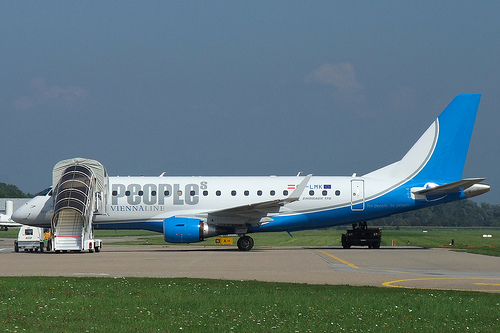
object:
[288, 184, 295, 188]
flag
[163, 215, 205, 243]
engine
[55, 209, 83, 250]
stairs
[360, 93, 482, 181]
tail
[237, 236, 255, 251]
gear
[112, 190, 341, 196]
windows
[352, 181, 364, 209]
door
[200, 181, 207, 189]
big s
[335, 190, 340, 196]
last window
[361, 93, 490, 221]
back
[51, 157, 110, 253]
staircase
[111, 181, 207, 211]
peoples viennaline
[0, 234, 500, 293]
ground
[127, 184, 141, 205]
e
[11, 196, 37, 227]
nose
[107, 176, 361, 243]
side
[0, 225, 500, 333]
outside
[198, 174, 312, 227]
wings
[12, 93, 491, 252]
aircraft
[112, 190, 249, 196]
seats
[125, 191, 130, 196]
window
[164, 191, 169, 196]
window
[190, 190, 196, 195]
window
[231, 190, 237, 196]
window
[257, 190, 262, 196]
window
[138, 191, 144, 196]
window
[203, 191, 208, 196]
window